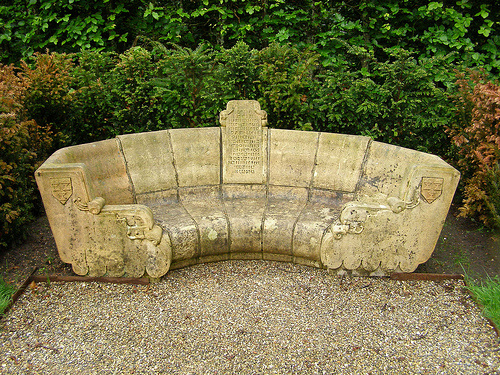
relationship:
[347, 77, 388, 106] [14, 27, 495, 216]
leaves in tree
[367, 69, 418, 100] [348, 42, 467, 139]
leaves in tree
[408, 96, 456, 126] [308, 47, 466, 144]
leaves in tree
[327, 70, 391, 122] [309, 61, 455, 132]
leaves in tree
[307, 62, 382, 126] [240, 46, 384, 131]
leaves in tree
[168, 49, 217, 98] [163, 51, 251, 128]
leaves in tree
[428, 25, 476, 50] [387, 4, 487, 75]
leaves in tree